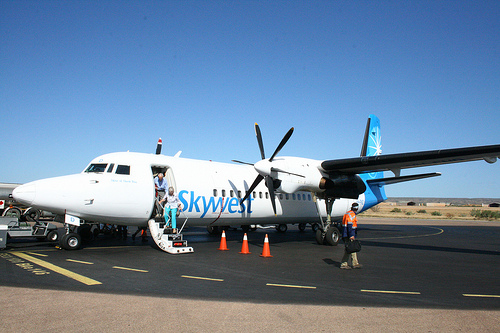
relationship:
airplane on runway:
[11, 112, 499, 258] [22, 243, 497, 308]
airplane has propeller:
[11, 112, 499, 258] [226, 122, 299, 214]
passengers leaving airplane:
[152, 170, 181, 236] [11, 112, 499, 258]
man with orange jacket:
[338, 203, 364, 272] [336, 211, 360, 241]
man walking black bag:
[338, 203, 364, 272] [344, 238, 362, 254]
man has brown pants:
[338, 203, 364, 272] [337, 251, 362, 270]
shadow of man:
[320, 254, 339, 272] [338, 203, 364, 272]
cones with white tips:
[213, 227, 276, 260] [214, 230, 273, 245]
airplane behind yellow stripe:
[11, 112, 499, 258] [4, 248, 102, 293]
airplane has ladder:
[11, 112, 499, 258] [144, 217, 194, 258]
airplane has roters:
[11, 112, 499, 258] [226, 122, 299, 214]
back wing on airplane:
[370, 170, 444, 187] [11, 112, 499, 258]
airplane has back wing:
[11, 112, 499, 258] [370, 170, 444, 187]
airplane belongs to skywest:
[11, 112, 499, 258] [177, 187, 257, 219]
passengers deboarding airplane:
[152, 170, 181, 236] [11, 112, 499, 258]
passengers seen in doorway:
[152, 170, 181, 236] [150, 162, 178, 223]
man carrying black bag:
[338, 203, 364, 272] [338, 238, 364, 255]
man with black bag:
[338, 203, 364, 272] [338, 238, 364, 255]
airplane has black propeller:
[11, 112, 499, 258] [226, 122, 299, 214]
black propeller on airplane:
[226, 122, 299, 214] [11, 112, 499, 258]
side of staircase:
[148, 220, 176, 256] [144, 217, 194, 258]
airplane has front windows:
[11, 112, 499, 258] [83, 162, 136, 178]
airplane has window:
[11, 112, 499, 258] [209, 188, 220, 199]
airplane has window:
[11, 112, 499, 258] [220, 189, 227, 200]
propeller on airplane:
[226, 122, 299, 214] [11, 112, 499, 258]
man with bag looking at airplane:
[338, 203, 364, 272] [11, 112, 499, 258]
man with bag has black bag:
[338, 203, 364, 272] [344, 238, 362, 254]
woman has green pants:
[160, 187, 181, 236] [163, 206, 177, 231]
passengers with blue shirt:
[154, 172, 181, 234] [153, 177, 168, 193]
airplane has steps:
[11, 112, 499, 258] [156, 217, 187, 246]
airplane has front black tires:
[11, 112, 499, 258] [45, 229, 83, 253]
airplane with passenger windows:
[11, 112, 499, 258] [209, 185, 322, 204]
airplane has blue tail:
[11, 112, 499, 258] [357, 114, 387, 217]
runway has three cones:
[22, 243, 497, 308] [213, 227, 276, 260]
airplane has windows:
[11, 112, 499, 258] [209, 185, 322, 204]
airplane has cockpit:
[11, 112, 499, 258] [84, 156, 144, 188]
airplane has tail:
[11, 112, 499, 258] [357, 114, 387, 217]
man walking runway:
[338, 203, 364, 272] [0, 217, 500, 333]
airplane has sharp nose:
[11, 112, 499, 258] [9, 178, 94, 217]